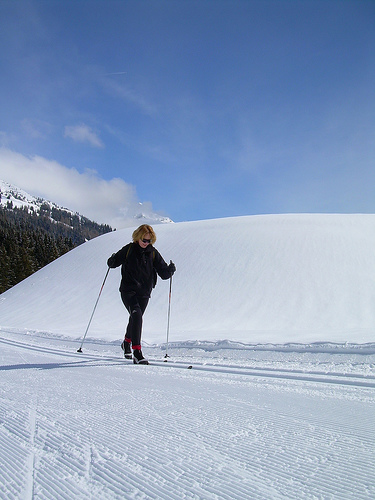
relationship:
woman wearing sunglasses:
[101, 223, 177, 368] [142, 238, 153, 242]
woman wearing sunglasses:
[107, 222, 176, 367] [142, 238, 153, 242]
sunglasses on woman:
[133, 237, 154, 247] [101, 223, 177, 368]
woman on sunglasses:
[101, 223, 177, 368] [142, 238, 153, 242]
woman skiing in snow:
[101, 223, 177, 368] [1, 207, 370, 495]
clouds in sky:
[0, 115, 147, 229] [3, 2, 374, 212]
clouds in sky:
[16, 160, 147, 229] [3, 2, 374, 212]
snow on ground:
[1, 207, 370, 495] [1, 208, 370, 495]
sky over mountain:
[3, 2, 374, 212] [1, 184, 111, 283]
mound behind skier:
[4, 214, 372, 333] [98, 223, 178, 364]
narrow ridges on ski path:
[15, 368, 330, 496] [1, 340, 372, 496]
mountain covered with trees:
[1, 184, 117, 299] [1, 222, 52, 272]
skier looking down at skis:
[98, 223, 178, 364] [98, 358, 191, 370]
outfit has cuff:
[103, 240, 166, 353] [117, 332, 143, 351]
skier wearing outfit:
[98, 223, 178, 364] [103, 240, 166, 353]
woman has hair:
[101, 223, 177, 368] [130, 223, 157, 248]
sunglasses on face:
[142, 238, 153, 242] [135, 228, 153, 247]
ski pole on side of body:
[85, 262, 175, 360] [114, 246, 164, 344]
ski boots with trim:
[119, 340, 151, 369] [126, 353, 153, 362]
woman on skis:
[107, 222, 176, 367] [98, 334, 191, 371]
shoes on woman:
[97, 335, 167, 373] [107, 222, 176, 367]